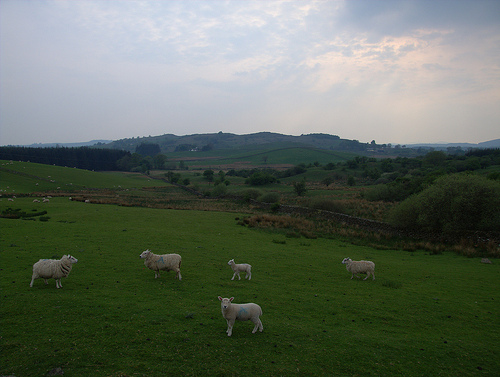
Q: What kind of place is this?
A: It is a field.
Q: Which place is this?
A: It is a field.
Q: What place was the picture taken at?
A: It was taken at the field.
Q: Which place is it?
A: It is a field.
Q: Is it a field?
A: Yes, it is a field.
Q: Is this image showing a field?
A: Yes, it is showing a field.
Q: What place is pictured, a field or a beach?
A: It is a field.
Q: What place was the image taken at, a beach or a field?
A: It was taken at a field.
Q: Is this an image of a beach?
A: No, the picture is showing a field.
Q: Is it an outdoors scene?
A: Yes, it is outdoors.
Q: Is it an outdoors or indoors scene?
A: It is outdoors.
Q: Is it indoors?
A: No, it is outdoors.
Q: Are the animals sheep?
A: Yes, all the animals are sheep.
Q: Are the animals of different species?
A: No, all the animals are sheep.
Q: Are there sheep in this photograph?
A: Yes, there is a sheep.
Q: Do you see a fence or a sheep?
A: Yes, there is a sheep.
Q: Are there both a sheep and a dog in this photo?
A: No, there is a sheep but no dogs.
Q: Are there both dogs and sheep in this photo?
A: No, there is a sheep but no dogs.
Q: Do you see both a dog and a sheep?
A: No, there is a sheep but no dogs.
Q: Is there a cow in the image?
A: No, there are no cows.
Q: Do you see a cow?
A: No, there are no cows.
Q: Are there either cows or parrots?
A: No, there are no cows or parrots.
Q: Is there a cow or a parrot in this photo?
A: No, there are no cows or parrots.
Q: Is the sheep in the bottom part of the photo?
A: Yes, the sheep is in the bottom of the image.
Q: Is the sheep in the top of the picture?
A: No, the sheep is in the bottom of the image.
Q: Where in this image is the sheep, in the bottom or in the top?
A: The sheep is in the bottom of the image.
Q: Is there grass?
A: Yes, there is grass.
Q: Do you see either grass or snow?
A: Yes, there is grass.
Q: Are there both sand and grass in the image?
A: No, there is grass but no sand.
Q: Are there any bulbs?
A: No, there are no bulbs.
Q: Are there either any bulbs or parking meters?
A: No, there are no bulbs or parking meters.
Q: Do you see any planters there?
A: No, there are no planters.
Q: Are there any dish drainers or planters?
A: No, there are no planters or dish drainers.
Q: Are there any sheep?
A: Yes, there is a sheep.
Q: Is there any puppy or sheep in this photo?
A: Yes, there is a sheep.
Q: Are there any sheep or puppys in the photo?
A: Yes, there is a sheep.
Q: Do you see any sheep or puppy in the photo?
A: Yes, there is a sheep.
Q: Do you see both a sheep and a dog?
A: No, there is a sheep but no dogs.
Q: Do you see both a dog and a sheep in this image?
A: No, there is a sheep but no dogs.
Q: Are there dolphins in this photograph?
A: No, there are no dolphins.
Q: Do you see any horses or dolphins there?
A: No, there are no dolphins or horses.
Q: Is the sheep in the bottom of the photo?
A: Yes, the sheep is in the bottom of the image.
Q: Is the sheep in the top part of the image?
A: No, the sheep is in the bottom of the image.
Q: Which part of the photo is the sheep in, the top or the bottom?
A: The sheep is in the bottom of the image.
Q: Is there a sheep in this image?
A: Yes, there is a sheep.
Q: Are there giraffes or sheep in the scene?
A: Yes, there is a sheep.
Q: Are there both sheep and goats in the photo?
A: No, there is a sheep but no goats.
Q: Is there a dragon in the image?
A: No, there are no dragons.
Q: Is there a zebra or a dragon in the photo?
A: No, there are no dragons or zebras.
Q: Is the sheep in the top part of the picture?
A: No, the sheep is in the bottom of the image.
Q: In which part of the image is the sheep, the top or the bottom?
A: The sheep is in the bottom of the image.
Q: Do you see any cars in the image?
A: No, there are no cars.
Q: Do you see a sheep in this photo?
A: Yes, there is a sheep.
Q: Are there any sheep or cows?
A: Yes, there is a sheep.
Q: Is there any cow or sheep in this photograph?
A: Yes, there is a sheep.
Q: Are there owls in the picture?
A: No, there are no owls.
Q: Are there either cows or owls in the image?
A: No, there are no owls or cows.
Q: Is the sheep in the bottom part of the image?
A: Yes, the sheep is in the bottom of the image.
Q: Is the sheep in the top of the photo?
A: No, the sheep is in the bottom of the image.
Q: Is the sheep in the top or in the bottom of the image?
A: The sheep is in the bottom of the image.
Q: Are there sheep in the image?
A: Yes, there is a sheep.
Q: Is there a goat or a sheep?
A: Yes, there is a sheep.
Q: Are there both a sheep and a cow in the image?
A: No, there is a sheep but no cows.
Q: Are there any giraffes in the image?
A: No, there are no giraffes.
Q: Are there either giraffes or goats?
A: No, there are no giraffes or goats.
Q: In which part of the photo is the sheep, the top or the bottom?
A: The sheep is in the bottom of the image.